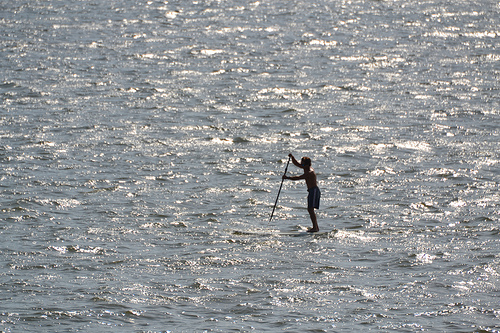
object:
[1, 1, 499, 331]
water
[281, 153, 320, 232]
man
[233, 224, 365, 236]
paddle board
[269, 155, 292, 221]
paddle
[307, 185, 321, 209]
swimming trunks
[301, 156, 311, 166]
hair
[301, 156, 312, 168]
head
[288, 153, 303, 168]
arm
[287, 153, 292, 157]
hand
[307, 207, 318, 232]
leg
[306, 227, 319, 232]
foot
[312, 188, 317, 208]
stripe